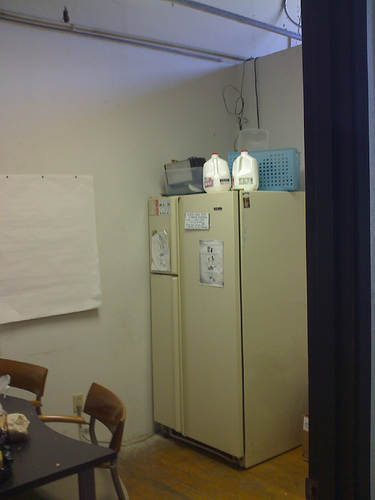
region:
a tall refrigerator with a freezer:
[146, 190, 303, 468]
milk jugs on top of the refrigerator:
[196, 146, 264, 192]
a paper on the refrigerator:
[192, 237, 226, 289]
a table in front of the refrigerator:
[1, 385, 113, 499]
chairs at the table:
[4, 346, 145, 498]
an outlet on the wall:
[69, 393, 84, 413]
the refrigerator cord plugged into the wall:
[71, 403, 167, 448]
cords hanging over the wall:
[216, 54, 267, 150]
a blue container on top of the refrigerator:
[226, 149, 300, 191]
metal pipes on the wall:
[0, 2, 296, 59]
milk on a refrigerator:
[228, 147, 258, 195]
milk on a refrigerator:
[191, 133, 228, 200]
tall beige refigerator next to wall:
[150, 192, 263, 472]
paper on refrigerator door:
[190, 234, 225, 302]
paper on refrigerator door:
[177, 207, 212, 234]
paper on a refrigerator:
[150, 222, 167, 282]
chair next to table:
[67, 373, 134, 437]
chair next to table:
[15, 350, 49, 399]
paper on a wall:
[28, 155, 123, 322]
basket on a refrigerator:
[266, 143, 301, 201]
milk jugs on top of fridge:
[201, 152, 270, 191]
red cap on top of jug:
[238, 146, 251, 155]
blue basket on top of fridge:
[228, 148, 293, 193]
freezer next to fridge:
[139, 196, 182, 466]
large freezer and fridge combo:
[142, 188, 310, 454]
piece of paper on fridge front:
[187, 235, 228, 295]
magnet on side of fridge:
[230, 189, 255, 209]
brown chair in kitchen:
[44, 389, 138, 494]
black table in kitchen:
[0, 378, 114, 490]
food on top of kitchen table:
[0, 396, 32, 468]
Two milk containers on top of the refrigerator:
[136, 137, 324, 247]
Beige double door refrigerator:
[140, 193, 314, 467]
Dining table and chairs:
[0, 350, 148, 499]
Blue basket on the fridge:
[221, 134, 297, 197]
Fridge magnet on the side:
[238, 190, 267, 213]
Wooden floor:
[152, 451, 231, 489]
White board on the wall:
[0, 156, 117, 323]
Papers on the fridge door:
[145, 199, 229, 297]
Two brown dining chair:
[4, 347, 145, 494]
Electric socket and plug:
[70, 390, 89, 430]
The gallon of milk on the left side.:
[205, 140, 232, 189]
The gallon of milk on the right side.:
[234, 151, 256, 189]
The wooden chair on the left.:
[4, 356, 50, 407]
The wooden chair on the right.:
[33, 386, 123, 456]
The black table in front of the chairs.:
[4, 385, 114, 493]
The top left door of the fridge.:
[152, 197, 184, 280]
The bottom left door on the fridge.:
[150, 271, 180, 424]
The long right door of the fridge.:
[173, 197, 248, 456]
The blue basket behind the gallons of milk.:
[231, 149, 300, 186]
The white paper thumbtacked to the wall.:
[1, 168, 101, 317]